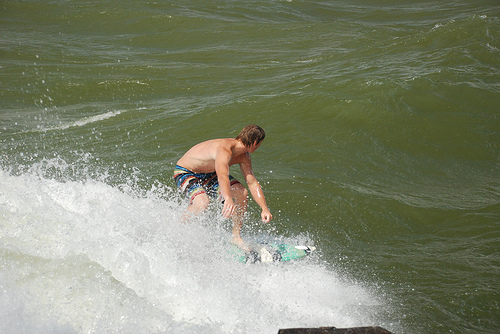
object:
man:
[147, 77, 324, 325]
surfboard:
[225, 240, 317, 267]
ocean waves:
[2, 1, 497, 332]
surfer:
[170, 124, 271, 256]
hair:
[235, 124, 265, 149]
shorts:
[167, 168, 240, 206]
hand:
[258, 210, 273, 225]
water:
[2, 4, 500, 330]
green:
[330, 112, 379, 204]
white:
[104, 236, 179, 303]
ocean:
[3, 10, 493, 330]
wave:
[2, 147, 411, 329]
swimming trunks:
[171, 168, 245, 195]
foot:
[227, 231, 247, 243]